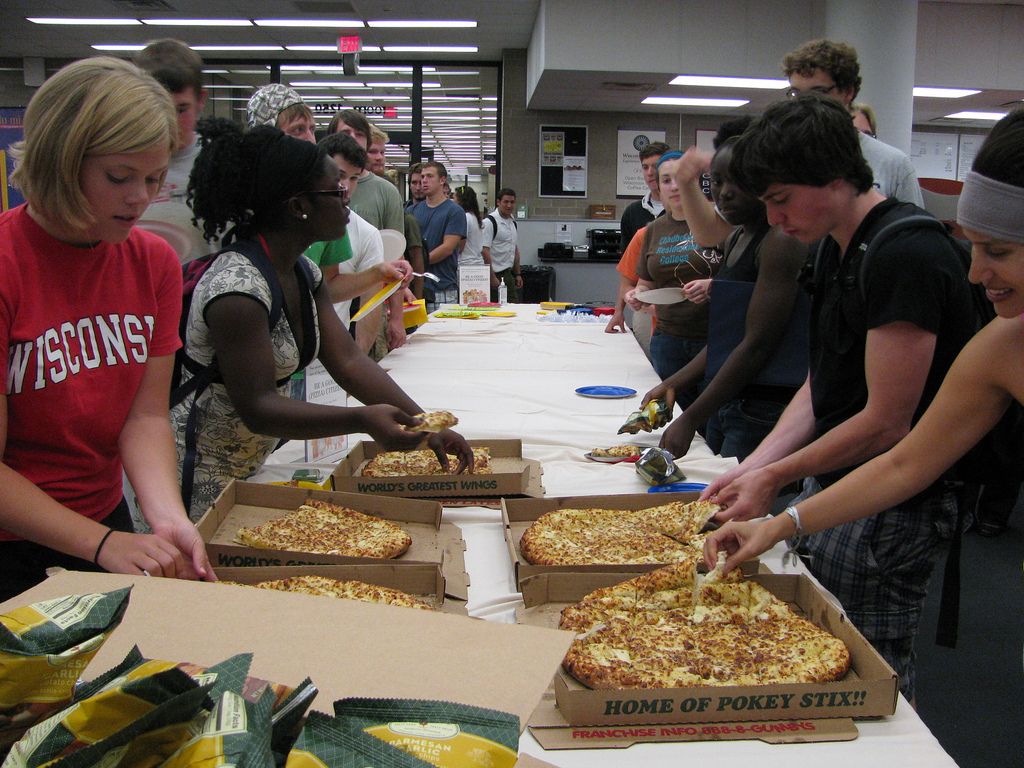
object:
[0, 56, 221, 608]
person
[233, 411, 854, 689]
pizza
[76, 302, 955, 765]
table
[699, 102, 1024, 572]
lady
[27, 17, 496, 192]
lights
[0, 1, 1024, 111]
ceiling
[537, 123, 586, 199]
pictures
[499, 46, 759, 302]
wall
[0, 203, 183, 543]
shirt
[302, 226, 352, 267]
shirt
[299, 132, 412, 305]
boy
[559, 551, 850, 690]
pizza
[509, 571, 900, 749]
box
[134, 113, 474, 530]
woman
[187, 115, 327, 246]
dread locks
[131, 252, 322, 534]
dress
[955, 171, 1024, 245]
grey headband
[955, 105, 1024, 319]
woman's head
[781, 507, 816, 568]
silver bracelet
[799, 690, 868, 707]
green word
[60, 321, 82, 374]
white c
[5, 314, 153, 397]
wisconsin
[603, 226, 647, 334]
right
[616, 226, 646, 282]
sleeve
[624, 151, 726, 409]
person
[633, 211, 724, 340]
shirt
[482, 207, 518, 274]
shirt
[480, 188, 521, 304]
person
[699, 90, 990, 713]
man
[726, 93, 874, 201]
hair